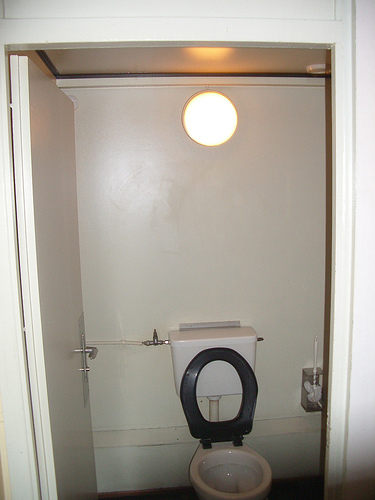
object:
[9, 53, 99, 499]
door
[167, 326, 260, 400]
tank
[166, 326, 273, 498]
toilet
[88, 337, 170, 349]
pipe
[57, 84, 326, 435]
wall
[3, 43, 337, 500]
bathroom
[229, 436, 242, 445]
hinges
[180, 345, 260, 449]
black seat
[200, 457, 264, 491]
water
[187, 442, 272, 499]
toilet bowl